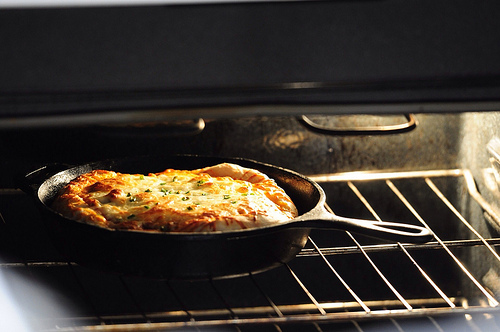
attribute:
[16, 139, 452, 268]
skillet — cast iron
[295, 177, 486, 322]
rack — wire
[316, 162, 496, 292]
rack — gray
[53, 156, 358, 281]
cheese — melting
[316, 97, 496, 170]
oven light — on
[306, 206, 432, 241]
handle — black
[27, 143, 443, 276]
food — cooked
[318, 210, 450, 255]
handle — metal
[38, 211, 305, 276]
pan — metal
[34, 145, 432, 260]
iron skillet — cast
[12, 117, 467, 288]
skillet — inside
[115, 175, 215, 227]
garnish — green